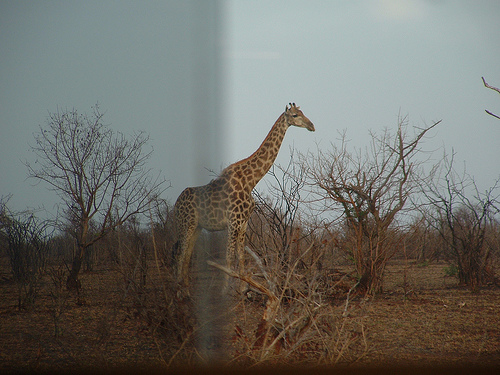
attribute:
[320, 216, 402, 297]
bushes — tall, brown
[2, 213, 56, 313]
bushes — brown, tall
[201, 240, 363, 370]
bushes — brown, tall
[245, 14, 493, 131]
sky — blue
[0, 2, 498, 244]
clouds — white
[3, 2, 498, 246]
sky — blue,  blue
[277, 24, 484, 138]
clouds — white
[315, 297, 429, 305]
dirt — brown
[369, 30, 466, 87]
clouds — white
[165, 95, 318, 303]
giraffe — patterned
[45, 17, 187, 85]
clouds — white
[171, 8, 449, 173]
sky — blue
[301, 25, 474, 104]
clouds — white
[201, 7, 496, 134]
cloud — white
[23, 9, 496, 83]
clouds — white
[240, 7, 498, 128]
cloud — white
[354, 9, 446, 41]
cloud — white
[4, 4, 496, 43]
sky — blue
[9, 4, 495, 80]
sky — blue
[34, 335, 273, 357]
leaves — brown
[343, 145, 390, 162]
leaves — brown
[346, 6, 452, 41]
cloud — white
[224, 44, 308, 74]
cloud — white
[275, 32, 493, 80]
cloud — white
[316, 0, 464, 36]
cloud — white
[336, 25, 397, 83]
cloud — white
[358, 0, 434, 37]
cloud — white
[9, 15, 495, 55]
sky — blue